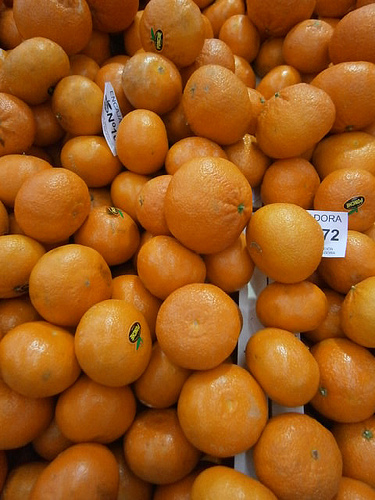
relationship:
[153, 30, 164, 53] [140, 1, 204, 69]
sticker on orange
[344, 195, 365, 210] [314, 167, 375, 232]
sticker on orange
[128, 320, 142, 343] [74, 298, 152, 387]
sticker on orange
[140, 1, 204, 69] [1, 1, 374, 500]
orange in cart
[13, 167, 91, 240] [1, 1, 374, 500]
orange in cart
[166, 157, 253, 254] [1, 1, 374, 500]
orange in cart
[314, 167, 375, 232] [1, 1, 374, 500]
orange in cart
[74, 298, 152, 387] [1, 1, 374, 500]
orange in cart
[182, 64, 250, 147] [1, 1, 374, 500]
orange in cart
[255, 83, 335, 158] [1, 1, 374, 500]
orange in cart